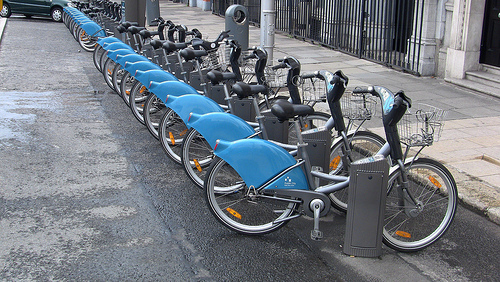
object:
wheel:
[50, 8, 64, 22]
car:
[0, 0, 74, 22]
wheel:
[158, 108, 212, 168]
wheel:
[93, 44, 113, 77]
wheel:
[77, 28, 101, 53]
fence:
[210, 0, 426, 77]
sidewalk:
[0, 0, 498, 282]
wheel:
[203, 156, 301, 235]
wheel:
[180, 127, 244, 195]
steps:
[443, 64, 499, 100]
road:
[63, 93, 499, 282]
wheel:
[143, 93, 197, 145]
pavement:
[316, 42, 499, 188]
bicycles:
[93, 17, 458, 252]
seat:
[271, 99, 314, 124]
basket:
[397, 102, 446, 146]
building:
[188, 1, 499, 98]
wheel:
[382, 158, 458, 252]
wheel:
[129, 80, 178, 128]